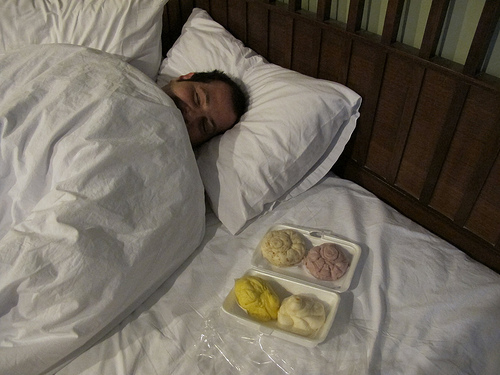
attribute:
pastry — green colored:
[267, 224, 307, 263]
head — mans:
[166, 71, 248, 130]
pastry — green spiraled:
[252, 225, 309, 271]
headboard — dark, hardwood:
[158, 0, 498, 273]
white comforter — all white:
[1, 42, 186, 372]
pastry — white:
[281, 293, 326, 338]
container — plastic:
[174, 199, 411, 371]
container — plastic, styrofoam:
[219, 221, 361, 344]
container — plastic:
[230, 223, 357, 353]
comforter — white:
[2, 45, 208, 370]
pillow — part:
[266, 94, 343, 154]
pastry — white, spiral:
[238, 234, 357, 307]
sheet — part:
[417, 241, 444, 307]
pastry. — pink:
[254, 225, 352, 264]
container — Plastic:
[216, 219, 368, 350]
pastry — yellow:
[229, 277, 269, 309]